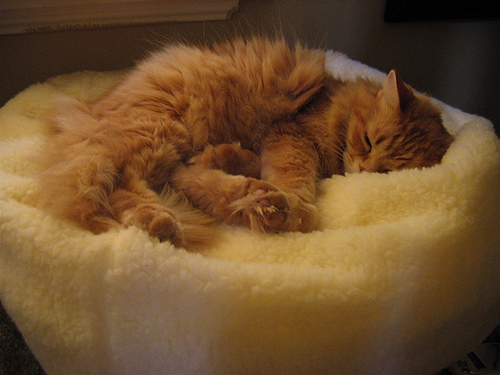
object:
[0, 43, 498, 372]
bed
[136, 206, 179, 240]
paw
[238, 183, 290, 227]
paw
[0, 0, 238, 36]
white trim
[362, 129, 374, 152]
eye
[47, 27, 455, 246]
cat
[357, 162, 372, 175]
nose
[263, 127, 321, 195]
leg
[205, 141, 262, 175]
leg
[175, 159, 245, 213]
leg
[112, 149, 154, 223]
leg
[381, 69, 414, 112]
ear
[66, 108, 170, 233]
tail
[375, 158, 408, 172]
eye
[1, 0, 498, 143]
wall